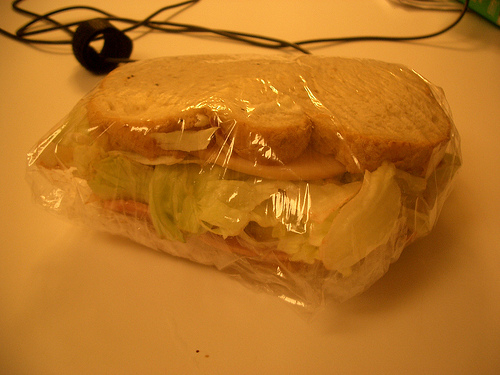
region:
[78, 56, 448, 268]
This is a sandwich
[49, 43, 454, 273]
The sandwich is wrapped in plastic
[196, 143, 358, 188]
The meat on the sandwich is turkey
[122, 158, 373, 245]
There is lettuce on the sandwich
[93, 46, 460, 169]
The sandwich is made with white bread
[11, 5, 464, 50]
There is a black cord behind the sandwich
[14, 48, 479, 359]
The sandwich is sitting on a white surface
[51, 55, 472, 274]
None of the sandwich has been eaten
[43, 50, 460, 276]
Plastic is around the sandwich to keep it fresh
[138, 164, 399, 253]
This is iceberg lettuce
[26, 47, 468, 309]
a sandwich in a plastic bag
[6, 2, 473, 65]
a cord on the table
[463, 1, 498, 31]
a green object in the corner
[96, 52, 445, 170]
bread on top of the table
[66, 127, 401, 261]
lettuce in the sandwich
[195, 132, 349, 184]
ham in the sandwich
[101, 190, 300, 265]
meat under the lettuce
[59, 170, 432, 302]
bread under the lettuce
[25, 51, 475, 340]
the plastic is shiny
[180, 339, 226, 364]
a speck on the table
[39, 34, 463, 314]
a plastic wrapper with sandwich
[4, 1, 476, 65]
a bunch of cables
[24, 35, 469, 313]
sandwich inside food wrapping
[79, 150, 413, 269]
lettuces inside sandwich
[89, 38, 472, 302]
a sandwich with ham and lettuces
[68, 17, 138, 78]
a cable organizer on table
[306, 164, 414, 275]
pieces of a lettuce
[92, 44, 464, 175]
a slice of bread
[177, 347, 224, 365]
sandwich crumbs on table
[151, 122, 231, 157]
pieces of lettuce sticking out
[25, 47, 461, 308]
sandwich enclosed in plastic wrap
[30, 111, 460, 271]
white and pale leaves of iceberg lettuce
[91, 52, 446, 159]
tan bread with brown crust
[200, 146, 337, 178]
curve of sliced meat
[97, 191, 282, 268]
pink slices of meat on top of bread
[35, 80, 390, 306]
light reflecting off the plastic wrap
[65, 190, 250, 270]
edge curled under with wrapping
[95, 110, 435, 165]
three curves on edge of bread with dark flecks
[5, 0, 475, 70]
tangled black wire with black ring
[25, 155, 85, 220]
excess plastic at corner